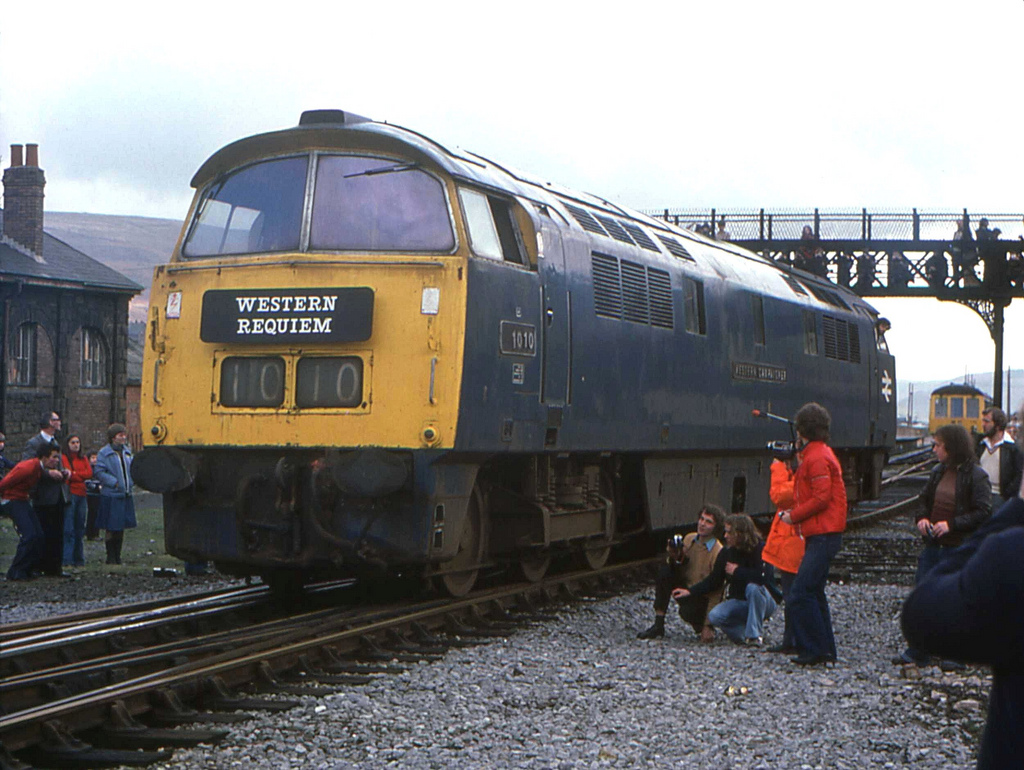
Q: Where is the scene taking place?
A: Train station.